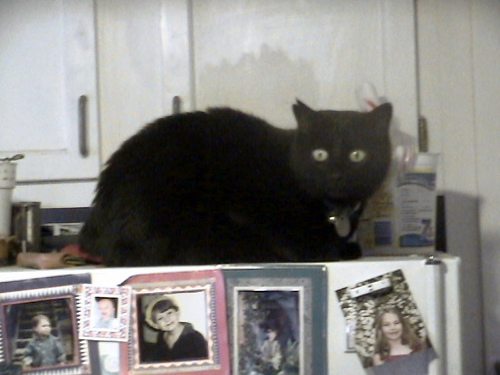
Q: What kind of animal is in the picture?
A: Cat.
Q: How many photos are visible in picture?
A: 5.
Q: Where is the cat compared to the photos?
A: Above.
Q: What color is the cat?
A: Black.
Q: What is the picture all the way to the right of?
A: Girl.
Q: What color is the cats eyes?
A: Green.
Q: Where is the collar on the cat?
A: Neck.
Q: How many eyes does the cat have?
A: 2.